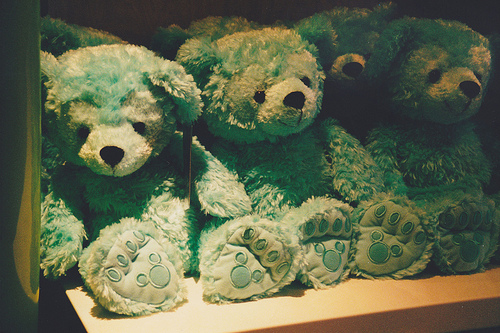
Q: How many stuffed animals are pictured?
A: Six.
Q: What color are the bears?
A: Green.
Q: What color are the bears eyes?
A: Black.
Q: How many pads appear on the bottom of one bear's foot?
A: Seven.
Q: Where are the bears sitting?
A: On a shelf.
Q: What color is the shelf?
A: Beige.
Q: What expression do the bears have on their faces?
A: Smiling.